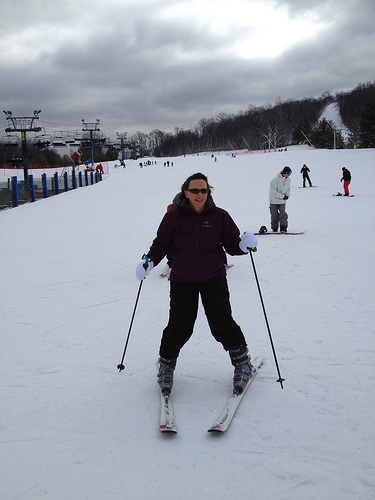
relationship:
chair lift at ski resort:
[0, 108, 132, 190] [0, 3, 373, 498]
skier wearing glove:
[134, 173, 260, 396] [237, 231, 258, 254]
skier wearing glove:
[134, 173, 260, 396] [136, 254, 154, 281]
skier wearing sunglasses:
[134, 173, 260, 396] [185, 186, 210, 196]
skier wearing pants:
[267, 166, 291, 232] [267, 203, 289, 232]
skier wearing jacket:
[267, 166, 291, 232] [268, 173, 290, 207]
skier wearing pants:
[339, 167, 352, 195] [341, 181, 350, 196]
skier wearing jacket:
[339, 167, 352, 195] [341, 169, 351, 180]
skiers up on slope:
[139, 159, 175, 169] [2, 147, 374, 499]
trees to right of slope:
[122, 81, 374, 158] [2, 147, 374, 499]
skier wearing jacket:
[134, 173, 260, 396] [145, 192, 250, 281]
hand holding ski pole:
[137, 258, 155, 281] [117, 254, 154, 374]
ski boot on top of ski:
[158, 355, 178, 395] [157, 364, 178, 437]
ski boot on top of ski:
[229, 346, 255, 395] [206, 354, 266, 435]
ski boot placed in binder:
[158, 355, 178, 395] [160, 381, 171, 395]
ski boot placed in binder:
[229, 346, 255, 395] [233, 366, 258, 394]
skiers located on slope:
[139, 159, 175, 169] [2, 147, 374, 499]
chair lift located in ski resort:
[0, 108, 132, 190] [0, 3, 373, 498]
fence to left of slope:
[0, 169, 103, 214] [2, 147, 374, 499]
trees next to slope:
[122, 81, 374, 158] [2, 147, 374, 499]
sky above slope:
[2, 2, 373, 153] [2, 147, 374, 499]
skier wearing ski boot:
[134, 173, 260, 396] [158, 355, 178, 395]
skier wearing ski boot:
[134, 173, 260, 396] [229, 346, 255, 395]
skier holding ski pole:
[134, 173, 260, 396] [117, 254, 154, 374]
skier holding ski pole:
[134, 173, 260, 396] [243, 230, 285, 388]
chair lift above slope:
[0, 108, 132, 190] [2, 147, 374, 499]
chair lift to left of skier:
[0, 108, 132, 190] [134, 173, 260, 396]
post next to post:
[12, 175, 20, 208] [28, 173, 37, 202]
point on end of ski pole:
[279, 381, 286, 391] [243, 230, 285, 388]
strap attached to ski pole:
[142, 253, 149, 265] [117, 254, 154, 374]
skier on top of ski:
[134, 173, 260, 396] [207, 354, 266, 434]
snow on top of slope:
[0, 142, 374, 500] [2, 147, 374, 499]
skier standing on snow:
[134, 173, 260, 396] [313, 101, 353, 141]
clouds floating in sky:
[0, 0, 375, 132] [2, 2, 373, 153]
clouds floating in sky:
[4, 23, 92, 59] [2, 2, 373, 153]